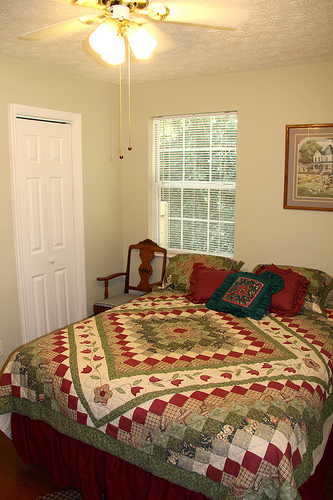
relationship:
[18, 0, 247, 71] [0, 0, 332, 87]
fan on ceiling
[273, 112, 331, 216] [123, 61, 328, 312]
painting on wall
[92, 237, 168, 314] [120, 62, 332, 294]
chair against wall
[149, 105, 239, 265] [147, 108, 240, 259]
window over window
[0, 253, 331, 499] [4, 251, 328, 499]
bedspread on bed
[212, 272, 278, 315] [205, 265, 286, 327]
cover on pillows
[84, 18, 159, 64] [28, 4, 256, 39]
lights under fan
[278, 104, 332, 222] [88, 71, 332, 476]
frame on wall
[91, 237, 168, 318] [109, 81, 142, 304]
chair in corner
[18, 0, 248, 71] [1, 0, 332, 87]
fan on cieling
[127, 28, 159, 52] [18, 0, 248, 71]
light on fan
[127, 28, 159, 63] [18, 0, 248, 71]
light on fan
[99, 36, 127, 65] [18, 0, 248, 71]
light on fan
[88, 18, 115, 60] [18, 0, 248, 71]
lights on fan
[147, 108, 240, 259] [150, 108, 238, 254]
window let enter sunlight